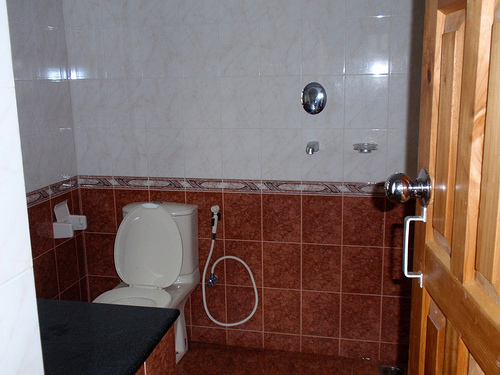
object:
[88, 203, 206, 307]
toilet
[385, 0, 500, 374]
door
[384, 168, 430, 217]
knob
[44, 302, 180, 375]
counter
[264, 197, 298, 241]
tiles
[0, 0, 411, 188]
wall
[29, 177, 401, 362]
red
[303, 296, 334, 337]
tile